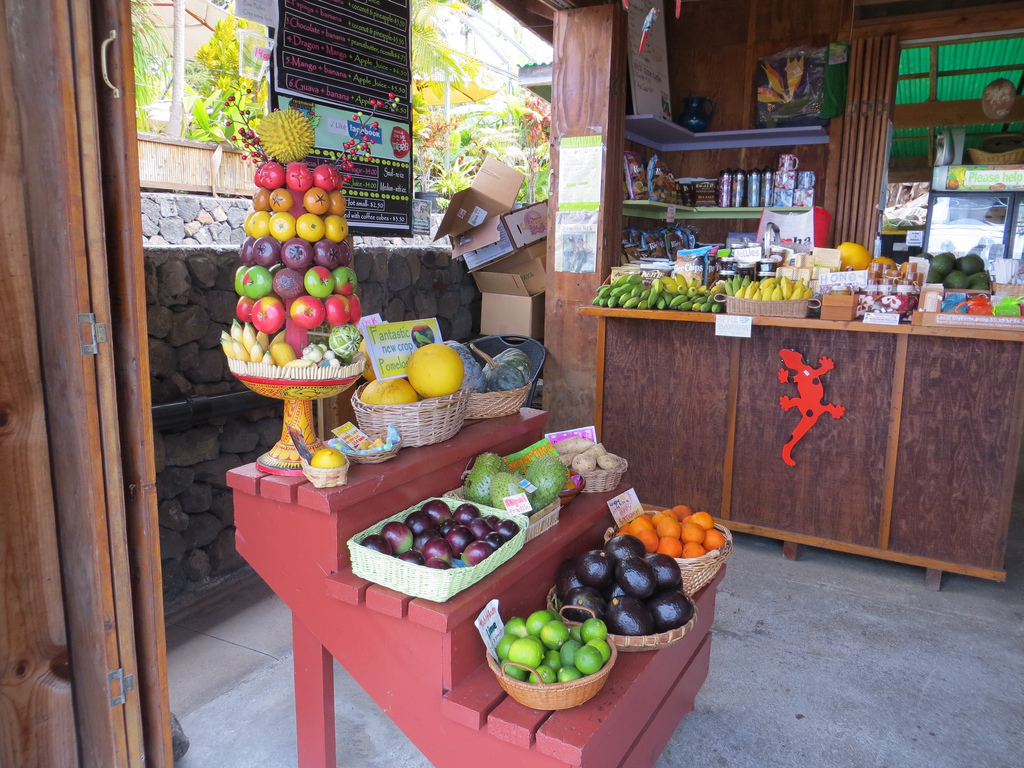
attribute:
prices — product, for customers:
[266, 12, 456, 240]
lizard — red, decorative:
[781, 323, 862, 497]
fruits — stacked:
[212, 132, 350, 380]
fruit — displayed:
[247, 345, 729, 687]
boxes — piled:
[444, 155, 550, 327]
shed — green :
[882, 34, 1022, 104]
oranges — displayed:
[623, 493, 723, 551]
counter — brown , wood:
[582, 284, 1022, 599]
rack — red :
[212, 378, 725, 767]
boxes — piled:
[437, 139, 551, 365]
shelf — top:
[598, 179, 856, 229]